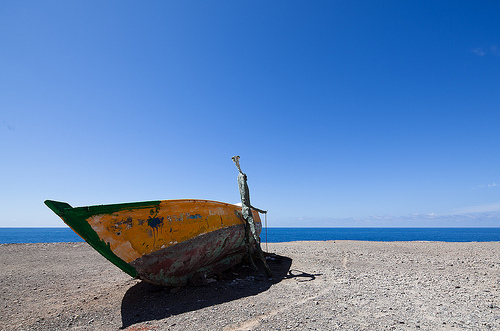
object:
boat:
[44, 154, 263, 285]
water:
[1, 228, 499, 242]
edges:
[44, 199, 135, 288]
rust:
[128, 221, 263, 288]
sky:
[0, 0, 499, 229]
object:
[230, 155, 273, 280]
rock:
[315, 298, 320, 304]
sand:
[0, 239, 499, 331]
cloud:
[470, 45, 499, 58]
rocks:
[342, 286, 347, 288]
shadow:
[118, 250, 324, 330]